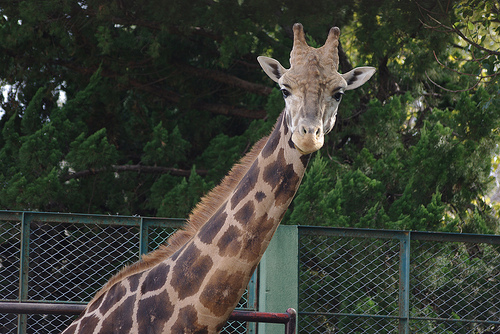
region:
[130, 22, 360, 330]
A tall brown giraffe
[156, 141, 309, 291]
A tall brown giraffe's neck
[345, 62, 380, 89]
A tall brown giraffe's ear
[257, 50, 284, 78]
A tall brown giraffe's ear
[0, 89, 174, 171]
A green tree branch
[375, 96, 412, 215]
A green tree branch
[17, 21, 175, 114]
A green tree branch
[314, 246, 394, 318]
A wire mesh fance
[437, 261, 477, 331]
A wire mesh fence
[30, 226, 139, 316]
A wire mesh fence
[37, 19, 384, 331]
a giraffe facing forwards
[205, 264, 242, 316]
this spot is light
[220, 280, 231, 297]
a white dot in the spot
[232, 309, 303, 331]
a red bar by the giraffe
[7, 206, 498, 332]
a fence behind the giraffe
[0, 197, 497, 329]
the fence is green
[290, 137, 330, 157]
his nose is white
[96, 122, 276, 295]
he has a brown mane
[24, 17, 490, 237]
a tree behind the fence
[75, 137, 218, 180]
a branch in the tree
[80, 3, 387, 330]
A long giraffe's neck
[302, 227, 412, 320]
A blue wire meshed fance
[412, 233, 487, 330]
A blue wire meshed fance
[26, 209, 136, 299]
A blue wire meshed fance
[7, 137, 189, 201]
A green leafy tree branch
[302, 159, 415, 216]
A green leafy tree branch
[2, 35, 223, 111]
A green leafy tree branch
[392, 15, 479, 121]
A green leafy tree branch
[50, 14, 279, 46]
A green leafy tree branch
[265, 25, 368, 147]
A small giraffe's head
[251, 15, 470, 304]
the girrafeis brown in colour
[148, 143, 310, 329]
it has white patterns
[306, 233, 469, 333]
the chain is green in colour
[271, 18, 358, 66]
it has two horns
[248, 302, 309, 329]
the railing is red in colour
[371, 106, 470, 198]
the trees are green in colour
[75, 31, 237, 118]
the branches are brown in colour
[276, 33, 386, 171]
the head is brown in colour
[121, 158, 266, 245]
it has brown hair on the back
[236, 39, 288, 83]
its ears are black on the inside